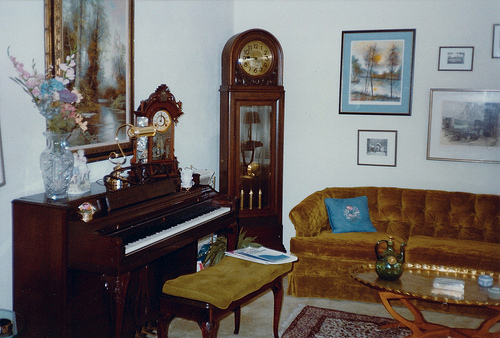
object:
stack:
[222, 238, 303, 265]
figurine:
[374, 234, 406, 279]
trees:
[361, 45, 381, 107]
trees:
[77, 11, 100, 137]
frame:
[340, 27, 413, 117]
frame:
[356, 128, 397, 168]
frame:
[428, 87, 498, 165]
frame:
[41, 0, 142, 162]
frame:
[437, 46, 476, 73]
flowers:
[41, 77, 63, 93]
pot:
[39, 128, 76, 200]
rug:
[277, 297, 432, 338]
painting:
[336, 31, 411, 112]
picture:
[440, 100, 498, 146]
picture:
[437, 44, 476, 73]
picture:
[340, 26, 413, 110]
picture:
[40, 4, 143, 162]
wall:
[0, 2, 232, 179]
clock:
[238, 40, 272, 80]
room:
[2, 0, 500, 337]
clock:
[151, 109, 171, 133]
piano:
[9, 178, 237, 338]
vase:
[39, 130, 75, 198]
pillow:
[323, 197, 378, 234]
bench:
[160, 242, 297, 337]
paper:
[433, 279, 464, 290]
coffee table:
[350, 260, 498, 336]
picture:
[357, 129, 397, 164]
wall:
[233, 0, 498, 269]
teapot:
[375, 235, 407, 280]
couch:
[283, 185, 500, 316]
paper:
[223, 243, 298, 264]